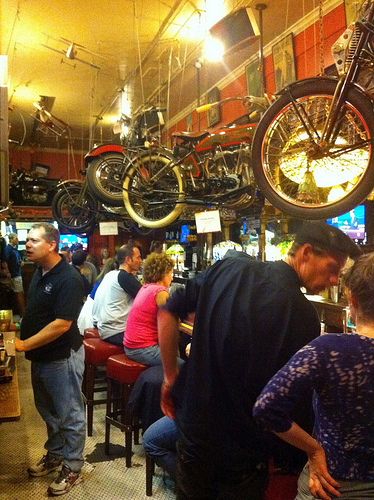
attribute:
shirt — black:
[11, 260, 84, 364]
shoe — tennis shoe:
[44, 463, 91, 498]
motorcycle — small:
[126, 84, 294, 226]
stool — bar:
[98, 336, 162, 483]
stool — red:
[99, 342, 151, 469]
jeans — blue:
[20, 346, 87, 495]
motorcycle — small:
[50, 165, 156, 236]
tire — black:
[220, 59, 373, 221]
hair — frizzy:
[142, 251, 179, 288]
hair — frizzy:
[341, 251, 373, 324]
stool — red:
[81, 337, 124, 436]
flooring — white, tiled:
[13, 383, 186, 498]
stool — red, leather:
[106, 340, 168, 449]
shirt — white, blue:
[89, 258, 131, 339]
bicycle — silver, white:
[113, 80, 292, 222]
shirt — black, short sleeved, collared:
[19, 252, 85, 360]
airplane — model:
[38, 20, 128, 87]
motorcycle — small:
[249, 0, 370, 220]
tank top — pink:
[123, 282, 166, 350]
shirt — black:
[158, 250, 319, 443]